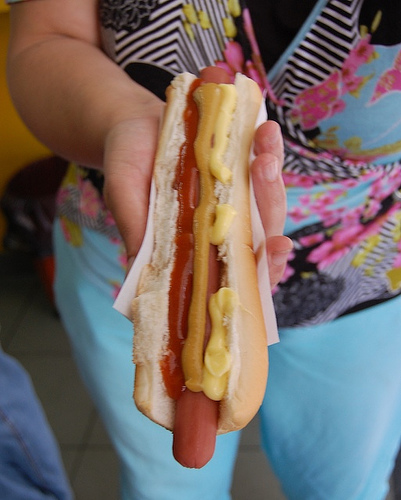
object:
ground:
[237, 453, 262, 499]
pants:
[54, 209, 399, 497]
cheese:
[206, 85, 234, 405]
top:
[52, 0, 400, 329]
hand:
[102, 100, 294, 290]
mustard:
[180, 81, 217, 393]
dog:
[173, 65, 236, 469]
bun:
[129, 62, 270, 469]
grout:
[69, 433, 94, 455]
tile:
[72, 439, 127, 496]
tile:
[238, 444, 271, 496]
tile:
[6, 292, 99, 449]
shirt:
[56, 0, 401, 329]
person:
[6, 0, 400, 495]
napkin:
[113, 96, 281, 347]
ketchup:
[158, 79, 200, 400]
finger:
[266, 235, 293, 290]